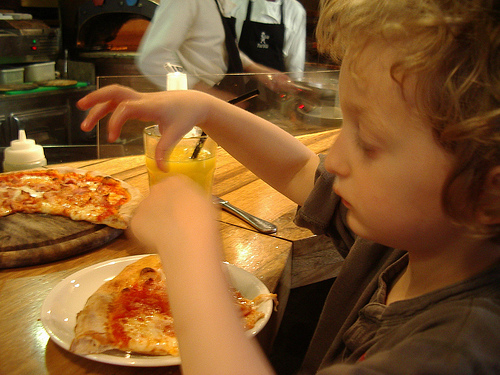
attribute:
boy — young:
[109, 19, 489, 367]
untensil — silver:
[193, 174, 306, 243]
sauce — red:
[114, 292, 157, 313]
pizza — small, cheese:
[0, 167, 143, 229]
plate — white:
[30, 243, 280, 370]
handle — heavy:
[221, 199, 278, 235]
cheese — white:
[120, 303, 266, 356]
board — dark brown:
[2, 164, 117, 265]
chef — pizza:
[132, 0, 309, 115]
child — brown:
[281, 20, 498, 365]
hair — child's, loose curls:
[351, 0, 498, 196]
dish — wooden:
[0, 203, 117, 270]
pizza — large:
[72, 252, 279, 357]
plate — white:
[40, 251, 272, 367]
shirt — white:
[222, 0, 305, 80]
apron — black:
[212, 1, 247, 97]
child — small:
[77, 0, 498, 372]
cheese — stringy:
[186, 277, 274, 335]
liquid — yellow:
[145, 148, 215, 201]